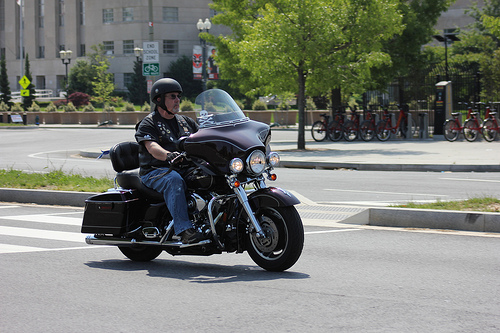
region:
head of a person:
[145, 74, 187, 128]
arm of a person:
[140, 122, 175, 163]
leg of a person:
[139, 172, 198, 219]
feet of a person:
[182, 225, 211, 245]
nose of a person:
[174, 97, 181, 108]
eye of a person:
[162, 87, 184, 100]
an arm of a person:
[147, 117, 185, 164]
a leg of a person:
[144, 175, 205, 239]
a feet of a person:
[171, 224, 207, 247]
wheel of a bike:
[234, 174, 338, 276]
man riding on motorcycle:
[84, 88, 311, 270]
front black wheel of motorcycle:
[242, 198, 314, 273]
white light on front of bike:
[245, 153, 269, 170]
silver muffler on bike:
[85, 235, 147, 253]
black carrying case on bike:
[67, 189, 139, 230]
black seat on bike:
[104, 142, 144, 186]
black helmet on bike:
[147, 76, 181, 103]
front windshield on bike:
[182, 81, 250, 136]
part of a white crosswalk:
[0, 205, 90, 260]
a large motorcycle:
[82, 85, 307, 274]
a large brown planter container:
[60, 111, 80, 123]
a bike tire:
[307, 115, 327, 145]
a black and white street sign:
[143, 40, 158, 62]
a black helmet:
[151, 76, 184, 110]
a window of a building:
[96, 8, 116, 24]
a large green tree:
[233, 1, 403, 149]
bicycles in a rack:
[300, 97, 442, 144]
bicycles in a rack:
[439, 97, 492, 150]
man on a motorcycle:
[60, 67, 305, 283]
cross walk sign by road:
[15, 70, 36, 114]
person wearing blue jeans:
[121, 144, 231, 248]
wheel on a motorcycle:
[235, 184, 307, 283]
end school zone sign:
[128, 38, 165, 80]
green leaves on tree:
[254, 5, 364, 147]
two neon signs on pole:
[17, 74, 32, 121]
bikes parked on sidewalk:
[293, 102, 495, 172]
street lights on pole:
[196, 16, 211, 89]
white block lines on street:
[0, 207, 84, 253]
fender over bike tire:
[245, 186, 302, 271]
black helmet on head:
[152, 77, 182, 115]